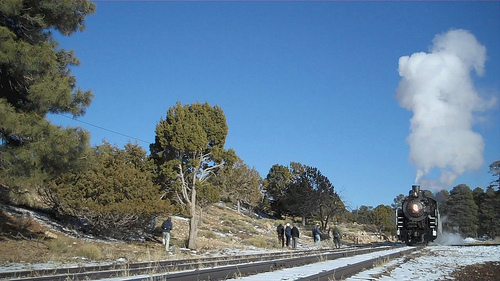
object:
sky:
[46, 0, 498, 214]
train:
[394, 185, 439, 246]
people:
[332, 225, 341, 249]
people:
[315, 225, 323, 243]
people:
[291, 223, 301, 250]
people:
[285, 223, 292, 247]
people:
[276, 224, 284, 249]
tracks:
[296, 247, 422, 281]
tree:
[151, 99, 228, 252]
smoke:
[393, 29, 498, 189]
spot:
[412, 204, 419, 212]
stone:
[43, 231, 57, 239]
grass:
[442, 261, 499, 281]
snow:
[377, 266, 415, 281]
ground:
[1, 241, 500, 280]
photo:
[1, 1, 500, 280]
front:
[393, 184, 439, 246]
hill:
[1, 173, 383, 273]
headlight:
[413, 204, 420, 211]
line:
[59, 113, 151, 144]